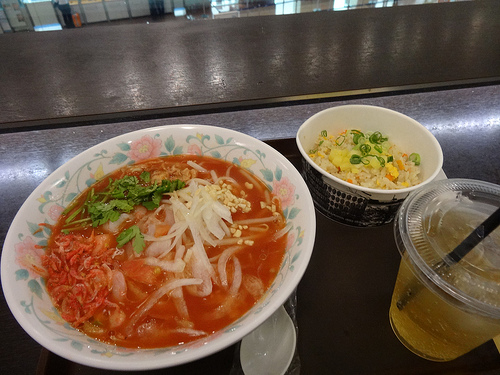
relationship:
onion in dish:
[126, 276, 203, 337] [3, 116, 322, 374]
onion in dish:
[169, 192, 219, 292] [3, 116, 322, 374]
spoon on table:
[235, 301, 299, 374] [3, 2, 499, 373]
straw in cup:
[396, 202, 500, 316] [385, 178, 499, 361]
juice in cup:
[386, 206, 499, 366] [385, 178, 499, 361]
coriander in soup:
[61, 170, 189, 256] [40, 154, 289, 355]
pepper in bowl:
[349, 154, 363, 167] [291, 104, 448, 232]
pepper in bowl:
[319, 127, 330, 141] [291, 104, 448, 232]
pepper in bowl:
[369, 128, 389, 147] [291, 104, 448, 232]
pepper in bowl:
[408, 148, 421, 167] [291, 104, 448, 232]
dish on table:
[3, 116, 322, 374] [3, 2, 499, 373]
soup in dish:
[40, 154, 289, 355] [3, 116, 322, 374]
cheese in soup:
[212, 184, 251, 213] [40, 154, 289, 355]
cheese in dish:
[212, 184, 251, 213] [3, 116, 322, 374]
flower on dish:
[123, 136, 164, 164] [3, 116, 322, 374]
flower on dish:
[271, 173, 296, 211] [3, 116, 322, 374]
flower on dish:
[14, 234, 47, 276] [3, 116, 322, 374]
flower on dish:
[48, 202, 67, 221] [3, 116, 322, 374]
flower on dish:
[38, 302, 68, 329] [3, 116, 322, 374]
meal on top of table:
[0, 102, 500, 370] [3, 2, 499, 373]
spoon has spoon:
[235, 301, 299, 374] [240, 304, 297, 374]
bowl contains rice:
[291, 104, 448, 232] [310, 127, 426, 192]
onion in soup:
[126, 276, 203, 337] [40, 154, 289, 355]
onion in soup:
[169, 192, 219, 292] [40, 154, 289, 355]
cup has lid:
[385, 178, 499, 361] [392, 176, 500, 326]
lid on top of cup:
[392, 176, 500, 326] [385, 178, 499, 361]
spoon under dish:
[235, 301, 299, 374] [3, 116, 322, 374]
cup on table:
[385, 178, 499, 361] [3, 2, 499, 373]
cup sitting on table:
[385, 178, 499, 361] [3, 2, 499, 373]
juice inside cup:
[386, 206, 499, 366] [385, 178, 499, 361]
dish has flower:
[3, 116, 322, 374] [123, 136, 164, 164]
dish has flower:
[3, 116, 322, 374] [271, 173, 296, 211]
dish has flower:
[3, 116, 322, 374] [38, 302, 68, 329]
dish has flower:
[3, 116, 322, 374] [14, 234, 47, 276]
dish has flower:
[3, 116, 322, 374] [48, 202, 67, 221]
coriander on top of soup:
[61, 170, 189, 256] [40, 154, 289, 355]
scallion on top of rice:
[358, 143, 374, 157] [310, 127, 426, 192]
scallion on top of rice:
[385, 156, 396, 165] [310, 127, 426, 192]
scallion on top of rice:
[350, 126, 367, 146] [310, 127, 426, 192]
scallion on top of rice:
[316, 140, 327, 150] [310, 127, 426, 192]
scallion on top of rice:
[374, 153, 386, 170] [310, 127, 426, 192]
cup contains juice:
[385, 178, 499, 361] [386, 206, 499, 366]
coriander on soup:
[61, 170, 189, 256] [40, 154, 289, 355]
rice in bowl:
[310, 127, 426, 192] [291, 104, 448, 232]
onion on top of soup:
[126, 276, 203, 337] [40, 154, 289, 355]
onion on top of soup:
[169, 192, 219, 292] [40, 154, 289, 355]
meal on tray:
[0, 102, 500, 370] [33, 132, 498, 374]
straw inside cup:
[396, 202, 500, 316] [385, 178, 499, 361]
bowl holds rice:
[291, 104, 448, 232] [310, 127, 426, 192]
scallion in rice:
[358, 143, 374, 157] [310, 127, 426, 192]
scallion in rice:
[316, 140, 327, 150] [310, 127, 426, 192]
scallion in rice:
[350, 126, 367, 146] [310, 127, 426, 192]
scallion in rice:
[385, 156, 396, 165] [310, 127, 426, 192]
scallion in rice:
[374, 153, 386, 170] [310, 127, 426, 192]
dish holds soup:
[3, 116, 322, 374] [40, 154, 289, 355]